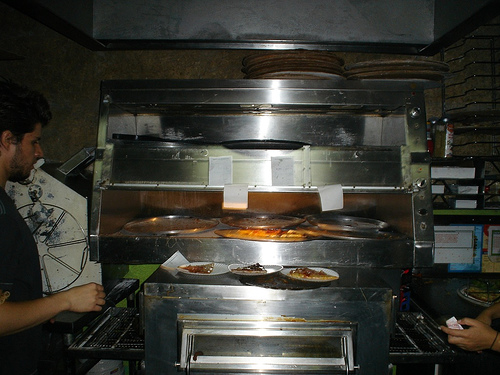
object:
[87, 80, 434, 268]
oven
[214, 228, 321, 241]
pizza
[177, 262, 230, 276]
plate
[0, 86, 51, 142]
hair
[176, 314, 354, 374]
door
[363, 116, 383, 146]
ticket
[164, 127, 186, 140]
spice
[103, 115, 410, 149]
shelf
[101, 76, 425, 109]
roof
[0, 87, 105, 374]
man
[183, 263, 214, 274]
food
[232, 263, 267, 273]
food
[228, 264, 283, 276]
plate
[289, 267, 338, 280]
pizza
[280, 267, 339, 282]
plate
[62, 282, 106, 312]
hand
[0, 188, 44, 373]
shirt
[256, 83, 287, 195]
light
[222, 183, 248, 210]
paper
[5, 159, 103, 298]
paper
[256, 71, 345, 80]
pan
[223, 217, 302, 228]
pizza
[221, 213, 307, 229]
pan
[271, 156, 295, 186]
order tag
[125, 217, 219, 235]
piece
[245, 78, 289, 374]
reflection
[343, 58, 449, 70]
object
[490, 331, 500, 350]
bracelet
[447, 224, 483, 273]
box